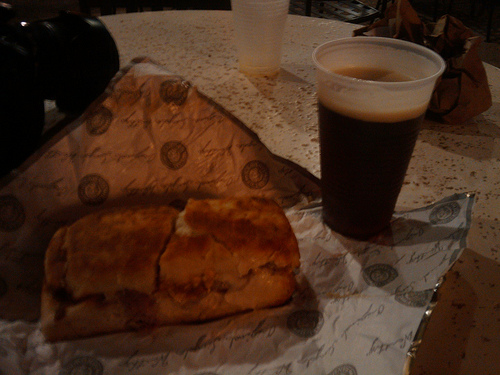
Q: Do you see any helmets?
A: No, there are no helmets.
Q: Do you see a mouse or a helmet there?
A: No, there are no helmets or computer mice.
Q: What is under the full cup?
A: The paper is under the cup.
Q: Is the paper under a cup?
A: Yes, the paper is under a cup.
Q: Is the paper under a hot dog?
A: No, the paper is under a cup.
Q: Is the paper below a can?
A: No, the paper is below a cup.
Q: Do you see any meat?
A: Yes, there is meat.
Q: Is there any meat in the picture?
A: Yes, there is meat.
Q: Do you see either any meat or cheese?
A: Yes, there is meat.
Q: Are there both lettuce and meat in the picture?
A: No, there is meat but no lettuce.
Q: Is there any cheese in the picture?
A: No, there is no cheese.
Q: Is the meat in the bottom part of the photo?
A: Yes, the meat is in the bottom of the image.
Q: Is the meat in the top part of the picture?
A: No, the meat is in the bottom of the image.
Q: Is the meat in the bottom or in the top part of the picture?
A: The meat is in the bottom of the image.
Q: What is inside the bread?
A: The meat is inside the bread.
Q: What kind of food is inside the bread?
A: The food is meat.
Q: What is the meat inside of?
A: The meat is inside the bread.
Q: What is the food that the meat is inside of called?
A: The food is a bread.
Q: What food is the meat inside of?
A: The meat is inside the bread.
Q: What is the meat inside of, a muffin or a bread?
A: The meat is inside a bread.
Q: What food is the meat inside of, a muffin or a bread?
A: The meat is inside a bread.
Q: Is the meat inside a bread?
A: Yes, the meat is inside a bread.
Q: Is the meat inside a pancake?
A: No, the meat is inside a bread.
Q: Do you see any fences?
A: No, there are no fences.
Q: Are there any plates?
A: No, there are no plates.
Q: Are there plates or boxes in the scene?
A: No, there are no plates or boxes.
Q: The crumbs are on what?
A: The crumbs are on the table.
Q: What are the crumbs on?
A: The crumbs are on the table.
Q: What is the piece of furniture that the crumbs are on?
A: The piece of furniture is a table.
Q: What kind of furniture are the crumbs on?
A: The crumbs are on the table.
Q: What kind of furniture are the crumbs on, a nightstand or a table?
A: The crumbs are on a table.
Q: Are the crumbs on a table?
A: Yes, the crumbs are on a table.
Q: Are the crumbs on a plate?
A: No, the crumbs are on a table.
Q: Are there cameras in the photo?
A: Yes, there is a camera.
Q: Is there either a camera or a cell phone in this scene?
A: Yes, there is a camera.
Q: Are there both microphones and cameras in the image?
A: No, there is a camera but no microphones.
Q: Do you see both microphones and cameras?
A: No, there is a camera but no microphones.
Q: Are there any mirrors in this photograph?
A: No, there are no mirrors.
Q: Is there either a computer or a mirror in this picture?
A: No, there are no mirrors or computers.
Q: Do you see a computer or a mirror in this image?
A: No, there are no mirrors or computers.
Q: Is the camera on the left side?
A: Yes, the camera is on the left of the image.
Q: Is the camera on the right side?
A: No, the camera is on the left of the image.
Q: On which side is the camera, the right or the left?
A: The camera is on the left of the image.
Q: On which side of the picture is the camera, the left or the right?
A: The camera is on the left of the image.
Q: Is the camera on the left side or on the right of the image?
A: The camera is on the left of the image.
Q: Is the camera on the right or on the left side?
A: The camera is on the left of the image.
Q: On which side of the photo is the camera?
A: The camera is on the left of the image.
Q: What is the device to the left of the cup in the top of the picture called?
A: The device is a camera.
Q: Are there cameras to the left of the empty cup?
A: Yes, there is a camera to the left of the cup.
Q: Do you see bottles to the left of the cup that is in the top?
A: No, there is a camera to the left of the cup.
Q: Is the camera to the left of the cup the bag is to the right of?
A: Yes, the camera is to the left of the cup.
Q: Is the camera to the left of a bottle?
A: No, the camera is to the left of the cup.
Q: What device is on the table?
A: The device is a camera.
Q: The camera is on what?
A: The camera is on the table.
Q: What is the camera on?
A: The camera is on the table.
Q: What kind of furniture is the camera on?
A: The camera is on the table.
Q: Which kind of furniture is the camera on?
A: The camera is on the table.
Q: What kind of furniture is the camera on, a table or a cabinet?
A: The camera is on a table.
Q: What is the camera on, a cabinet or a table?
A: The camera is on a table.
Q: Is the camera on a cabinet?
A: No, the camera is on the table.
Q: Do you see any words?
A: Yes, there are words.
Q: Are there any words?
A: Yes, there are words.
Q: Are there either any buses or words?
A: Yes, there are words.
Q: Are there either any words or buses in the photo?
A: Yes, there are words.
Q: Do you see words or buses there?
A: Yes, there are words.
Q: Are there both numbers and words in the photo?
A: No, there are words but no numbers.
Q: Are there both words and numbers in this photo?
A: No, there are words but no numbers.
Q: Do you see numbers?
A: No, there are no numbers.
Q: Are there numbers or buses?
A: No, there are no numbers or buses.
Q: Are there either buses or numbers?
A: No, there are no numbers or buses.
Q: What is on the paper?
A: The words are on the paper.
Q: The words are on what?
A: The words are on the paper.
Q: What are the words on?
A: The words are on the paper.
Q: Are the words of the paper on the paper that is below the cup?
A: Yes, the words are on the paper.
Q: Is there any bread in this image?
A: Yes, there is a bread.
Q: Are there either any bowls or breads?
A: Yes, there is a bread.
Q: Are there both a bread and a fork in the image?
A: No, there is a bread but no forks.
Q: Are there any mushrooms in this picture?
A: No, there are no mushrooms.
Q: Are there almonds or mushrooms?
A: No, there are no mushrooms or almonds.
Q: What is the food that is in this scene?
A: The food is a bread.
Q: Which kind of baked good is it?
A: The food is a bread.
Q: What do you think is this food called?
A: This is a bread.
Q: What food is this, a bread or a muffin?
A: This is a bread.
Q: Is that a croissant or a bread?
A: That is a bread.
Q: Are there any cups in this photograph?
A: Yes, there is a cup.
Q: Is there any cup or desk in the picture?
A: Yes, there is a cup.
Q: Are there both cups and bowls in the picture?
A: No, there is a cup but no bowls.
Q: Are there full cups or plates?
A: Yes, there is a full cup.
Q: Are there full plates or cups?
A: Yes, there is a full cup.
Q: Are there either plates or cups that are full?
A: Yes, the cup is full.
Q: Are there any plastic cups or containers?
A: Yes, there is a plastic cup.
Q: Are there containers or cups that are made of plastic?
A: Yes, the cup is made of plastic.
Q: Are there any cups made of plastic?
A: Yes, there is a cup that is made of plastic.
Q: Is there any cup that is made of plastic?
A: Yes, there is a cup that is made of plastic.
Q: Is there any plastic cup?
A: Yes, there is a cup that is made of plastic.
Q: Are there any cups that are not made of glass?
A: Yes, there is a cup that is made of plastic.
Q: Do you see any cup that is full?
A: Yes, there is a full cup.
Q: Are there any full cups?
A: Yes, there is a full cup.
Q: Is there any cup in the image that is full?
A: Yes, there is a cup that is full.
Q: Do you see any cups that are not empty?
A: Yes, there is an full cup.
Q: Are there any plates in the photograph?
A: No, there are no plates.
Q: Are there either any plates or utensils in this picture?
A: No, there are no plates or utensils.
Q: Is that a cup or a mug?
A: That is a cup.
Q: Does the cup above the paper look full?
A: Yes, the cup is full.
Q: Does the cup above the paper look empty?
A: No, the cup is full.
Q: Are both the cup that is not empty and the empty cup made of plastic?
A: Yes, both the cup and the cup are made of plastic.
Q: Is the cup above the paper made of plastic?
A: Yes, the cup is made of plastic.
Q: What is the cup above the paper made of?
A: The cup is made of plastic.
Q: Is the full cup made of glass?
A: No, the cup is made of plastic.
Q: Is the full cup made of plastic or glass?
A: The cup is made of plastic.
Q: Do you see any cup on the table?
A: Yes, there is a cup on the table.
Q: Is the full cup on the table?
A: Yes, the cup is on the table.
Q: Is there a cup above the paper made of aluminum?
A: Yes, there is a cup above the paper.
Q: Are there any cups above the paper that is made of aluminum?
A: Yes, there is a cup above the paper.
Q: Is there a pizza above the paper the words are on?
A: No, there is a cup above the paper.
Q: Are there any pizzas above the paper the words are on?
A: No, there is a cup above the paper.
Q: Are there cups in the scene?
A: Yes, there is a cup.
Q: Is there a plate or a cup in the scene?
A: Yes, there is a cup.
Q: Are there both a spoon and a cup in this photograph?
A: No, there is a cup but no spoons.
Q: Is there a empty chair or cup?
A: Yes, there is an empty cup.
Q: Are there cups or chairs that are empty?
A: Yes, the cup is empty.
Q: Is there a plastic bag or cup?
A: Yes, there is a plastic cup.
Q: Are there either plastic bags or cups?
A: Yes, there is a plastic cup.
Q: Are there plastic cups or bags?
A: Yes, there is a plastic cup.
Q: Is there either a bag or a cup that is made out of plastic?
A: Yes, the cup is made of plastic.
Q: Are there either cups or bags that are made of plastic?
A: Yes, the cup is made of plastic.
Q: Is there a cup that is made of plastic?
A: Yes, there is a cup that is made of plastic.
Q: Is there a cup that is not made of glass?
A: Yes, there is a cup that is made of plastic.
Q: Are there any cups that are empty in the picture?
A: Yes, there is an empty cup.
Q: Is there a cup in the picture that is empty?
A: Yes, there is a cup that is empty.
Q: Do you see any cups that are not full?
A: Yes, there is a empty cup.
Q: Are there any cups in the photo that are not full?
A: Yes, there is a empty cup.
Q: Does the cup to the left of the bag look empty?
A: Yes, the cup is empty.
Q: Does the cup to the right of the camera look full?
A: No, the cup is empty.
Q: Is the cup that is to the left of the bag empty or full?
A: The cup is empty.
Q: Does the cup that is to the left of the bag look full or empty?
A: The cup is empty.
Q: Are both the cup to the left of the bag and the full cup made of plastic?
A: Yes, both the cup and the cup are made of plastic.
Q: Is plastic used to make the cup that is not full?
A: Yes, the cup is made of plastic.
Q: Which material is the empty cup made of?
A: The cup is made of plastic.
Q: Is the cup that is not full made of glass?
A: No, the cup is made of plastic.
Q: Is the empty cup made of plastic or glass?
A: The cup is made of plastic.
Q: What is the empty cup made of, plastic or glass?
A: The cup is made of plastic.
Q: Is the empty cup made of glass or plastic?
A: The cup is made of plastic.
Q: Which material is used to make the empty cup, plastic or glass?
A: The cup is made of plastic.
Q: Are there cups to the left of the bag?
A: Yes, there is a cup to the left of the bag.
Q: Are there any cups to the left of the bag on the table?
A: Yes, there is a cup to the left of the bag.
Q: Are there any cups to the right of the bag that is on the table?
A: No, the cup is to the left of the bag.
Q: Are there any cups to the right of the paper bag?
A: No, the cup is to the left of the bag.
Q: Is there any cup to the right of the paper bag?
A: No, the cup is to the left of the bag.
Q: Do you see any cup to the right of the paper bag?
A: No, the cup is to the left of the bag.